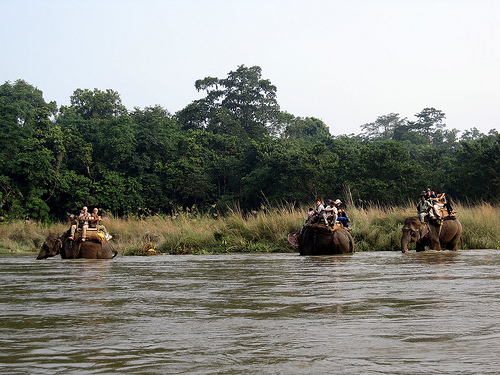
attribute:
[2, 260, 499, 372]
water — muddy, brown, moving, calm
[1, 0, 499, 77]
sky — clear, open, blue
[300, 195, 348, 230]
people — sitting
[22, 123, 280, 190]
leaves — green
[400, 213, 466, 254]
elephant — grey, gray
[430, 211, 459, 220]
seat — yellow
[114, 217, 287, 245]
grass — long, tall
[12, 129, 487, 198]
trees — green, lush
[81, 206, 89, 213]
hat — white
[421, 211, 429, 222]
pants — white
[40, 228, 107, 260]
elephant — gray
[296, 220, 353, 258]
elephant — gray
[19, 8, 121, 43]
clouds — white